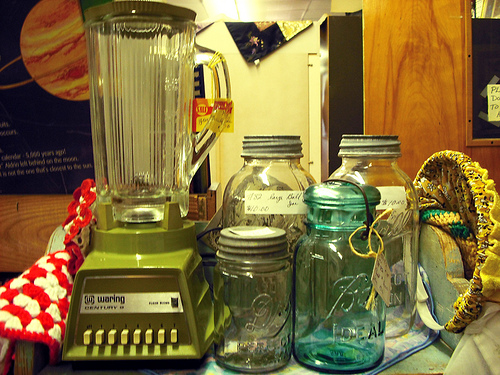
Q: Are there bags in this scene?
A: No, there are no bags.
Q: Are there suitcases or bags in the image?
A: No, there are no bags or suitcases.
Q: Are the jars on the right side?
A: Yes, the jars are on the right of the image.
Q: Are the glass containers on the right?
A: Yes, the jars are on the right of the image.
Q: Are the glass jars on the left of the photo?
A: No, the jars are on the right of the image.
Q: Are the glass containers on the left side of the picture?
A: No, the jars are on the right of the image.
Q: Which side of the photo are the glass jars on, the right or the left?
A: The jars are on the right of the image.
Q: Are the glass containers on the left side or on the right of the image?
A: The jars are on the right of the image.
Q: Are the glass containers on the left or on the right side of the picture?
A: The jars are on the right of the image.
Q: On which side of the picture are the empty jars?
A: The jars are on the right of the image.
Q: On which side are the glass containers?
A: The jars are on the right of the image.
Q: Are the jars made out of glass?
A: Yes, the jars are made of glass.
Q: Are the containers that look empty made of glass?
A: Yes, the jars are made of glass.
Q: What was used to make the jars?
A: The jars are made of glass.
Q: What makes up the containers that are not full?
A: The jars are made of glass.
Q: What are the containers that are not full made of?
A: The jars are made of glass.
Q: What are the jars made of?
A: The jars are made of glass.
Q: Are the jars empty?
A: Yes, the jars are empty.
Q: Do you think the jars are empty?
A: Yes, the jars are empty.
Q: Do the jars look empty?
A: Yes, the jars are empty.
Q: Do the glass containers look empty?
A: Yes, the jars are empty.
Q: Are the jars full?
A: No, the jars are empty.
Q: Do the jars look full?
A: No, the jars are empty.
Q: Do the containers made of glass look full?
A: No, the jars are empty.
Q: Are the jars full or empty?
A: The jars are empty.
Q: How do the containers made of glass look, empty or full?
A: The jars are empty.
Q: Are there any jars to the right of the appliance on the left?
A: Yes, there are jars to the right of the blender.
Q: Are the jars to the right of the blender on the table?
A: Yes, the jars are to the right of the blender.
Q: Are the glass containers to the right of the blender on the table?
A: Yes, the jars are to the right of the blender.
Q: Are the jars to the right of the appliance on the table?
A: Yes, the jars are to the right of the blender.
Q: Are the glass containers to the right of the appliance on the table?
A: Yes, the jars are to the right of the blender.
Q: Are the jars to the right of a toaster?
A: No, the jars are to the right of the blender.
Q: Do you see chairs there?
A: No, there are no chairs.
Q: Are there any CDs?
A: No, there are no cds.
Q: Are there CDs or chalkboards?
A: No, there are no CDs or chalkboards.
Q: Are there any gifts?
A: No, there are no gifts.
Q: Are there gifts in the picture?
A: No, there are no gifts.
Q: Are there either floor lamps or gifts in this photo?
A: No, there are no gifts or floor lamps.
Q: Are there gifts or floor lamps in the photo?
A: No, there are no gifts or floor lamps.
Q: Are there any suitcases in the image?
A: No, there are no suitcases.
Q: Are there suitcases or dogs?
A: No, there are no suitcases or dogs.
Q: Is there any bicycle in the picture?
A: No, there are no bicycles.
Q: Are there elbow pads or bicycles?
A: No, there are no bicycles or elbow pads.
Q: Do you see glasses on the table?
A: Yes, there are glasses on the table.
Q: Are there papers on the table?
A: No, there are glasses on the table.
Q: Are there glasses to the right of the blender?
A: Yes, there are glasses to the right of the blender.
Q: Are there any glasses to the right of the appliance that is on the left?
A: Yes, there are glasses to the right of the blender.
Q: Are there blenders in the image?
A: Yes, there is a blender.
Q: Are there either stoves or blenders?
A: Yes, there is a blender.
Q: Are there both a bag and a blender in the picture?
A: No, there is a blender but no bags.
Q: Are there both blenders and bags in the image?
A: No, there is a blender but no bags.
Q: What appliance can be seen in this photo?
A: The appliance is a blender.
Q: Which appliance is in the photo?
A: The appliance is a blender.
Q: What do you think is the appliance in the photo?
A: The appliance is a blender.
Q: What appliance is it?
A: The appliance is a blender.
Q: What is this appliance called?
A: This is a blender.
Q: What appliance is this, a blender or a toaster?
A: This is a blender.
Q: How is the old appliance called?
A: The appliance is a blender.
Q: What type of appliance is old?
A: The appliance is a blender.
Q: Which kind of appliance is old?
A: The appliance is a blender.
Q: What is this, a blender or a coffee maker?
A: This is a blender.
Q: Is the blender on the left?
A: Yes, the blender is on the left of the image.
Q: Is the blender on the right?
A: No, the blender is on the left of the image.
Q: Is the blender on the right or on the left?
A: The blender is on the left of the image.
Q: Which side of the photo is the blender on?
A: The blender is on the left of the image.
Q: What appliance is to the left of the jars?
A: The appliance is a blender.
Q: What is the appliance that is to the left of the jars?
A: The appliance is a blender.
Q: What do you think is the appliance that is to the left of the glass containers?
A: The appliance is a blender.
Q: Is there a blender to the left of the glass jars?
A: Yes, there is a blender to the left of the jars.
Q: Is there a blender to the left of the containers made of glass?
A: Yes, there is a blender to the left of the jars.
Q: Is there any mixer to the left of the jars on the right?
A: No, there is a blender to the left of the jars.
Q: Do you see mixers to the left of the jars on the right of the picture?
A: No, there is a blender to the left of the jars.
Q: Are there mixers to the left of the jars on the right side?
A: No, there is a blender to the left of the jars.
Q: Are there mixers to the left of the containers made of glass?
A: No, there is a blender to the left of the jars.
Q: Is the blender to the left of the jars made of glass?
A: Yes, the blender is to the left of the jars.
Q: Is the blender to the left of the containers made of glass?
A: Yes, the blender is to the left of the jars.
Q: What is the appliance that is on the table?
A: The appliance is a blender.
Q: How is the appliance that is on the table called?
A: The appliance is a blender.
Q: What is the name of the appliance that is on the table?
A: The appliance is a blender.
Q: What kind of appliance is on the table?
A: The appliance is a blender.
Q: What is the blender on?
A: The blender is on the table.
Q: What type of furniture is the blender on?
A: The blender is on the table.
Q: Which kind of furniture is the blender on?
A: The blender is on the table.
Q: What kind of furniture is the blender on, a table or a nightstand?
A: The blender is on a table.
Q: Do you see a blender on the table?
A: Yes, there is a blender on the table.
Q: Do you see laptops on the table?
A: No, there is a blender on the table.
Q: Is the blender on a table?
A: Yes, the blender is on a table.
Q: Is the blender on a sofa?
A: No, the blender is on a table.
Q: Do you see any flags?
A: No, there are no flags.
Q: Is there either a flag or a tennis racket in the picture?
A: No, there are no flags or rackets.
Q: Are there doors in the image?
A: Yes, there is a door.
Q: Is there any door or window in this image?
A: Yes, there is a door.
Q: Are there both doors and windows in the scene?
A: Yes, there are both a door and a window.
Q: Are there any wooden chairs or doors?
A: Yes, there is a wood door.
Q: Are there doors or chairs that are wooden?
A: Yes, the door is wooden.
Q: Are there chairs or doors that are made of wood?
A: Yes, the door is made of wood.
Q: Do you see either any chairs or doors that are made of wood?
A: Yes, the door is made of wood.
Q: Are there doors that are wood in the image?
A: Yes, there is a wood door.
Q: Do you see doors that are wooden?
A: Yes, there is a door that is wooden.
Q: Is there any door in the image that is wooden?
A: Yes, there is a door that is wooden.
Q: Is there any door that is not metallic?
A: Yes, there is a wooden door.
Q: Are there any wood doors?
A: Yes, there is a door that is made of wood.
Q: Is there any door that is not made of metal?
A: Yes, there is a door that is made of wood.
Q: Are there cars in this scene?
A: No, there are no cars.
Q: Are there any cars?
A: No, there are no cars.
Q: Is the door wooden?
A: Yes, the door is wooden.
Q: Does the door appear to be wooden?
A: Yes, the door is wooden.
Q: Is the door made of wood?
A: Yes, the door is made of wood.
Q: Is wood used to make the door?
A: Yes, the door is made of wood.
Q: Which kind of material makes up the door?
A: The door is made of wood.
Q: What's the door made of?
A: The door is made of wood.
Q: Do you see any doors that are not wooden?
A: No, there is a door but it is wooden.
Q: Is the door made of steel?
A: No, the door is made of wood.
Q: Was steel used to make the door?
A: No, the door is made of wood.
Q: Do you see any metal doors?
A: No, there is a door but it is made of wood.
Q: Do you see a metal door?
A: No, there is a door but it is made of wood.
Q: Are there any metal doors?
A: No, there is a door but it is made of wood.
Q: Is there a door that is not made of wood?
A: No, there is a door but it is made of wood.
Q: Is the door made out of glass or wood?
A: The door is made of wood.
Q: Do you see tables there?
A: Yes, there is a table.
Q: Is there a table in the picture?
A: Yes, there is a table.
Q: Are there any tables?
A: Yes, there is a table.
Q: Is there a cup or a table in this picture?
A: Yes, there is a table.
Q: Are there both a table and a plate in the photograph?
A: No, there is a table but no plates.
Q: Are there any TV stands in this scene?
A: No, there are no TV stands.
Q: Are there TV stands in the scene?
A: No, there are no TV stands.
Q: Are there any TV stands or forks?
A: No, there are no TV stands or forks.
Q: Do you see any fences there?
A: No, there are no fences.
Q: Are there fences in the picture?
A: No, there are no fences.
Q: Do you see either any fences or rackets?
A: No, there are no fences or rackets.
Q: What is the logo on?
A: The logo is on the blender.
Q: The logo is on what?
A: The logo is on the blender.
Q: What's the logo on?
A: The logo is on the blender.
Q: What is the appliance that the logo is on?
A: The appliance is a blender.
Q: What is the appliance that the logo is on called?
A: The appliance is a blender.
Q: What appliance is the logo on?
A: The logo is on the blender.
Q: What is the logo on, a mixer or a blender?
A: The logo is on a blender.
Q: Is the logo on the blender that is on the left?
A: Yes, the logo is on the blender.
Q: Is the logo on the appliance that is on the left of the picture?
A: Yes, the logo is on the blender.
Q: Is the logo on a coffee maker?
A: No, the logo is on the blender.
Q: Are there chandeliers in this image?
A: No, there are no chandeliers.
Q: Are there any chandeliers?
A: No, there are no chandeliers.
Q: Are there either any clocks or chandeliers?
A: No, there are no chandeliers or clocks.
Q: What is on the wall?
A: The poster is on the wall.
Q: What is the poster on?
A: The poster is on the wall.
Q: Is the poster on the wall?
A: Yes, the poster is on the wall.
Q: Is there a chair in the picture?
A: No, there are no chairs.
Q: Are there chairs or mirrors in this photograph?
A: No, there are no chairs or mirrors.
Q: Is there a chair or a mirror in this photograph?
A: No, there are no chairs or mirrors.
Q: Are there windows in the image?
A: Yes, there is a window.